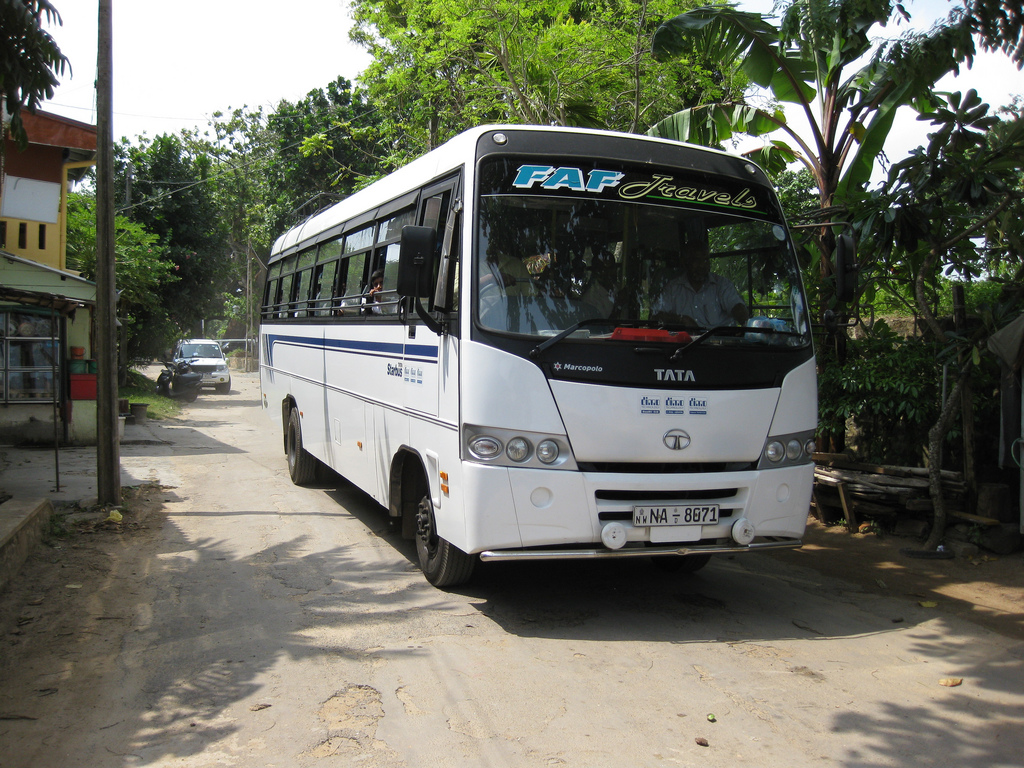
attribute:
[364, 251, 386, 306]
window — open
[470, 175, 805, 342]
windshield — reflective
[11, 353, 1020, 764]
street — partially shaded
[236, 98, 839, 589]
bus — white, big